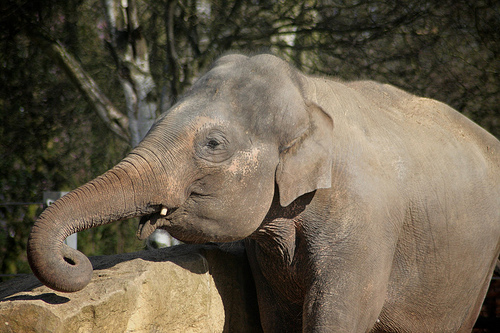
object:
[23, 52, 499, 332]
elephant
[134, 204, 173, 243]
mouth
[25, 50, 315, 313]
head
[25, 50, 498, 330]
skin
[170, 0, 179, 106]
branches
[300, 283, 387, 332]
leg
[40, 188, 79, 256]
pole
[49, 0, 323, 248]
bark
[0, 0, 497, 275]
building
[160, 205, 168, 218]
tooth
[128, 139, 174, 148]
wrinkles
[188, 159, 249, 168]
wrinkles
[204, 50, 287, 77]
hair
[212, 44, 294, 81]
mups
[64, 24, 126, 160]
moss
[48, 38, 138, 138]
branch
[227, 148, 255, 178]
marks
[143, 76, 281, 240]
face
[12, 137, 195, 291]
trunk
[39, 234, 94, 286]
bottom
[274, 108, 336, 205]
ear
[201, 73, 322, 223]
side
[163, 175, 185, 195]
spots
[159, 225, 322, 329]
shadow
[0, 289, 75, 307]
shadow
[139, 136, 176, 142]
lines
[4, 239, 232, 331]
rock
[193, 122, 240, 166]
eye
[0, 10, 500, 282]
tree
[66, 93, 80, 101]
leaves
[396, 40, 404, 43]
leaves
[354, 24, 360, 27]
leaves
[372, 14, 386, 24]
leaves